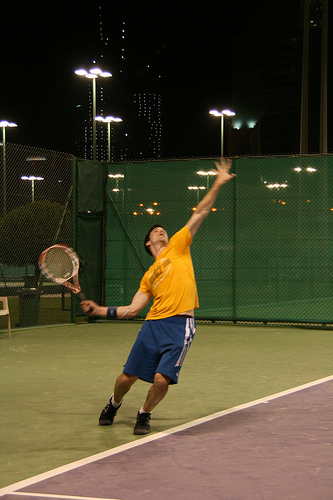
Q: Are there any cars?
A: No, there are no cars.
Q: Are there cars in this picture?
A: No, there are no cars.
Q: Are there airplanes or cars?
A: No, there are no cars or airplanes.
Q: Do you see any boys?
A: No, there are no boys.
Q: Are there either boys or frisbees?
A: No, there are no boys or frisbees.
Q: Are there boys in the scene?
A: No, there are no boys.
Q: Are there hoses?
A: No, there are no hoses.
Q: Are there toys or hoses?
A: No, there are no hoses or toys.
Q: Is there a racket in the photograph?
A: Yes, there is a racket.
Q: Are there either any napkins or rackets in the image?
A: Yes, there is a racket.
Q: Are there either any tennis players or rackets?
A: Yes, there is a tennis racket.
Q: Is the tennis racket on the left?
A: Yes, the racket is on the left of the image.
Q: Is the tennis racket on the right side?
A: No, the tennis racket is on the left of the image.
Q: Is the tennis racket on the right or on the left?
A: The tennis racket is on the left of the image.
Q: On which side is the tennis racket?
A: The racket is on the left of the image.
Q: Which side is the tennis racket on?
A: The racket is on the left of the image.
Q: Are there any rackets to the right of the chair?
A: Yes, there is a racket to the right of the chair.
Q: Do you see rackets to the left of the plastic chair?
A: No, the racket is to the right of the chair.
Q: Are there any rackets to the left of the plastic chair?
A: No, the racket is to the right of the chair.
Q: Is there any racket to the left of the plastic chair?
A: No, the racket is to the right of the chair.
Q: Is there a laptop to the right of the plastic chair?
A: No, there is a racket to the right of the chair.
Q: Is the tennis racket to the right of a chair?
A: Yes, the racket is to the right of a chair.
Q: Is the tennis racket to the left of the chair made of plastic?
A: No, the racket is to the right of the chair.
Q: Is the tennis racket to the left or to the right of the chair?
A: The racket is to the right of the chair.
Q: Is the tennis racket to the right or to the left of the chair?
A: The racket is to the right of the chair.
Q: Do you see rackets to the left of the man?
A: Yes, there is a racket to the left of the man.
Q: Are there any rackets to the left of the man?
A: Yes, there is a racket to the left of the man.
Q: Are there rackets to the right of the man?
A: No, the racket is to the left of the man.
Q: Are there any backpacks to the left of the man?
A: No, there is a racket to the left of the man.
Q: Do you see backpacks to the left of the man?
A: No, there is a racket to the left of the man.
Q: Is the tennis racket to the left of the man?
A: Yes, the racket is to the left of the man.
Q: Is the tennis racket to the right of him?
A: No, the tennis racket is to the left of the man.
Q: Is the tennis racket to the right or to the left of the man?
A: The tennis racket is to the left of the man.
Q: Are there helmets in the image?
A: No, there are no helmets.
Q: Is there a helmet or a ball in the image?
A: No, there are no helmets or balls.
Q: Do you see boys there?
A: No, there are no boys.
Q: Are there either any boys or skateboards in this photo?
A: No, there are no boys or skateboards.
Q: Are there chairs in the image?
A: Yes, there is a chair.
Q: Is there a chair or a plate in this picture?
A: Yes, there is a chair.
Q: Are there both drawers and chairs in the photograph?
A: No, there is a chair but no drawers.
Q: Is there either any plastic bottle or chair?
A: Yes, there is a plastic chair.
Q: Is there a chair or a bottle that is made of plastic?
A: Yes, the chair is made of plastic.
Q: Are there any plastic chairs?
A: Yes, there is a chair that is made of plastic.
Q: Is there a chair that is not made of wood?
A: Yes, there is a chair that is made of plastic.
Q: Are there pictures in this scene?
A: No, there are no pictures.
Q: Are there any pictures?
A: No, there are no pictures.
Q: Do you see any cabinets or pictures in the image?
A: No, there are no pictures or cabinets.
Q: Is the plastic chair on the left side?
A: Yes, the chair is on the left of the image.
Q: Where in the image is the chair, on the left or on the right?
A: The chair is on the left of the image.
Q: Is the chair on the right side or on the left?
A: The chair is on the left of the image.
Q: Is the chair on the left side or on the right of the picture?
A: The chair is on the left of the image.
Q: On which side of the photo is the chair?
A: The chair is on the left of the image.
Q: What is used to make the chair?
A: The chair is made of plastic.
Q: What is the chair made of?
A: The chair is made of plastic.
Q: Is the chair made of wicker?
A: No, the chair is made of plastic.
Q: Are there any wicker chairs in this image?
A: No, there is a chair but it is made of plastic.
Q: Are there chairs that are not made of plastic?
A: No, there is a chair but it is made of plastic.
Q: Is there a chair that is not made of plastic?
A: No, there is a chair but it is made of plastic.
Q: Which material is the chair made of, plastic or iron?
A: The chair is made of plastic.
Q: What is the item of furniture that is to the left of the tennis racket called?
A: The piece of furniture is a chair.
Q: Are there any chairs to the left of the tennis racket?
A: Yes, there is a chair to the left of the tennis racket.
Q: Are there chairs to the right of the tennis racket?
A: No, the chair is to the left of the tennis racket.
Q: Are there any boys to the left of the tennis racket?
A: No, there is a chair to the left of the tennis racket.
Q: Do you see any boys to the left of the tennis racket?
A: No, there is a chair to the left of the tennis racket.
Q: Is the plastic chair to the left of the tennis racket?
A: Yes, the chair is to the left of the racket.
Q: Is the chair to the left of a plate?
A: No, the chair is to the left of the racket.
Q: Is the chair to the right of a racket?
A: No, the chair is to the left of a racket.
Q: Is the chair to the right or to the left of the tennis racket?
A: The chair is to the left of the racket.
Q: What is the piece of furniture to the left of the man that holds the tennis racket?
A: The piece of furniture is a chair.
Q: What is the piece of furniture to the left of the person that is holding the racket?
A: The piece of furniture is a chair.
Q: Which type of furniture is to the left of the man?
A: The piece of furniture is a chair.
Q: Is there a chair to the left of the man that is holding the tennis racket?
A: Yes, there is a chair to the left of the man.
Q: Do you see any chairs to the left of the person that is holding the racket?
A: Yes, there is a chair to the left of the man.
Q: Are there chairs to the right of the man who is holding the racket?
A: No, the chair is to the left of the man.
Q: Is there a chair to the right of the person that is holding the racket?
A: No, the chair is to the left of the man.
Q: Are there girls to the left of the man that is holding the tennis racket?
A: No, there is a chair to the left of the man.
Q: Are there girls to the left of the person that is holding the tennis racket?
A: No, there is a chair to the left of the man.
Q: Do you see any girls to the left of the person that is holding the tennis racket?
A: No, there is a chair to the left of the man.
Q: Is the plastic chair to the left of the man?
A: Yes, the chair is to the left of the man.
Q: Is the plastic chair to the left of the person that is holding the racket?
A: Yes, the chair is to the left of the man.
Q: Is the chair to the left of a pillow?
A: No, the chair is to the left of the man.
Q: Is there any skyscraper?
A: Yes, there is a skyscraper.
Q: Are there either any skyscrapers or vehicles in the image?
A: Yes, there is a skyscraper.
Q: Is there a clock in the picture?
A: No, there are no clocks.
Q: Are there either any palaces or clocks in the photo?
A: No, there are no clocks or palaces.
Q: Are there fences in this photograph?
A: Yes, there is a fence.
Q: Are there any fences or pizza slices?
A: Yes, there is a fence.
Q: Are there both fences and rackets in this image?
A: Yes, there are both a fence and a racket.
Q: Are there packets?
A: No, there are no packets.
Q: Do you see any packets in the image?
A: No, there are no packets.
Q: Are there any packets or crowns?
A: No, there are no packets or crowns.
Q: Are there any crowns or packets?
A: No, there are no packets or crowns.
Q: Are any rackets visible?
A: Yes, there is a racket.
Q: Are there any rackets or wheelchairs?
A: Yes, there is a racket.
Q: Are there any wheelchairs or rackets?
A: Yes, there is a racket.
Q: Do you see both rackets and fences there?
A: Yes, there are both a racket and a fence.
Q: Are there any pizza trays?
A: No, there are no pizza trays.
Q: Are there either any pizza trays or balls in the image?
A: No, there are no pizza trays or balls.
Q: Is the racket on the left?
A: Yes, the racket is on the left of the image.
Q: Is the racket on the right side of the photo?
A: No, the racket is on the left of the image.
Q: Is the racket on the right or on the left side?
A: The racket is on the left of the image.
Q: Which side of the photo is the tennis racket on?
A: The tennis racket is on the left of the image.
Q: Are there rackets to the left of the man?
A: Yes, there is a racket to the left of the man.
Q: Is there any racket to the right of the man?
A: No, the racket is to the left of the man.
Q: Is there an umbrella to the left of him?
A: No, there is a racket to the left of the man.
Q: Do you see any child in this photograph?
A: No, there are no children.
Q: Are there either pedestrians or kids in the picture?
A: No, there are no kids or pedestrians.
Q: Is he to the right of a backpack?
A: No, the man is to the right of the racket.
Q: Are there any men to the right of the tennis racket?
A: Yes, there is a man to the right of the racket.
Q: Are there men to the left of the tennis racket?
A: No, the man is to the right of the tennis racket.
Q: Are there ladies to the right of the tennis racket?
A: No, there is a man to the right of the tennis racket.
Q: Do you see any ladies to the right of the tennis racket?
A: No, there is a man to the right of the tennis racket.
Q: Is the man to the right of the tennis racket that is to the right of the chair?
A: Yes, the man is to the right of the racket.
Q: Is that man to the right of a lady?
A: No, the man is to the right of the racket.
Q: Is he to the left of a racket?
A: No, the man is to the right of a racket.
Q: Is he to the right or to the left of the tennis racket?
A: The man is to the right of the racket.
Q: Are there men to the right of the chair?
A: Yes, there is a man to the right of the chair.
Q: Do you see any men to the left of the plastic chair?
A: No, the man is to the right of the chair.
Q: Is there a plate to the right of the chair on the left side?
A: No, there is a man to the right of the chair.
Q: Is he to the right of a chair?
A: Yes, the man is to the right of a chair.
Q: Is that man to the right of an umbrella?
A: No, the man is to the right of a chair.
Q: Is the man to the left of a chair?
A: No, the man is to the right of a chair.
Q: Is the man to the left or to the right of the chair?
A: The man is to the right of the chair.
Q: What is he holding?
A: The man is holding the tennis racket.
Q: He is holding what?
A: The man is holding the tennis racket.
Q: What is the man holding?
A: The man is holding the tennis racket.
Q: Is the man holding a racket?
A: Yes, the man is holding a racket.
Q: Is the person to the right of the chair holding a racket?
A: Yes, the man is holding a racket.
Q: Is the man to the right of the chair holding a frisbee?
A: No, the man is holding a racket.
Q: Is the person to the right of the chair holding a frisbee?
A: No, the man is holding a racket.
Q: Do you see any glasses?
A: No, there are no glasses.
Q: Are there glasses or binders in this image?
A: No, there are no glasses or binders.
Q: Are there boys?
A: No, there are no boys.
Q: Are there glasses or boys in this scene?
A: No, there are no boys or glasses.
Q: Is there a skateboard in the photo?
A: No, there are no skateboards.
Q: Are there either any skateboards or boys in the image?
A: No, there are no skateboards or boys.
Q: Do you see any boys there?
A: No, there are no boys.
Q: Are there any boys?
A: No, there are no boys.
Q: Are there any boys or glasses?
A: No, there are no boys or glasses.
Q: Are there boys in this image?
A: No, there are no boys.